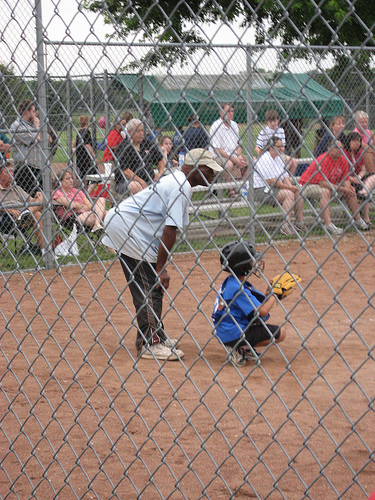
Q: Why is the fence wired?
A: Enclose the field.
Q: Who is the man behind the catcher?
A: Umpire.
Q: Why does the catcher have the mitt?
A: To catch ball.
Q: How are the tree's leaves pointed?
A: Downward.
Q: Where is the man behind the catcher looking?
A: Ahead.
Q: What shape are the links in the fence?
A: Diamond.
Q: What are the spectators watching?
A: Baseball game.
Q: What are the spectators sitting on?
A: Bleachers.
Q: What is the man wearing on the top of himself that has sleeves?
A: Shirt.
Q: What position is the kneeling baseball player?
A: Catcher.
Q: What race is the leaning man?
A: African.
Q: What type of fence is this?
A: Chain link.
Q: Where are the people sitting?
A: Bleachers.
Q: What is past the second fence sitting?
A: Is people.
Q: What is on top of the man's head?
A: Hat.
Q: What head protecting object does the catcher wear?
A: Helmet.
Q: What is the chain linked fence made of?
A: Metal.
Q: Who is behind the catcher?
A: The umpire.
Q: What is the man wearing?
A: Jogging pants.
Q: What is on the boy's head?
A: Helmet.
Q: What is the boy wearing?
A: A t-shirt.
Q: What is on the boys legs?
A: Shorts.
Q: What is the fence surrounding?
A: A field.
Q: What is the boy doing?
A: Waiting to catch.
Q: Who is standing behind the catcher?
A: A man.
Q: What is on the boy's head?
A: A helmet.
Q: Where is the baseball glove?
A: On the boy's hand.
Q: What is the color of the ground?
A: Brown.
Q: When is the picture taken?
A: Daytime.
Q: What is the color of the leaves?
A: Green.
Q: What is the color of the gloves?
A: Yellow.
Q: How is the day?
A: Sunny.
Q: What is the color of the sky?
A: White.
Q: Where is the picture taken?
A: At a baseball game.